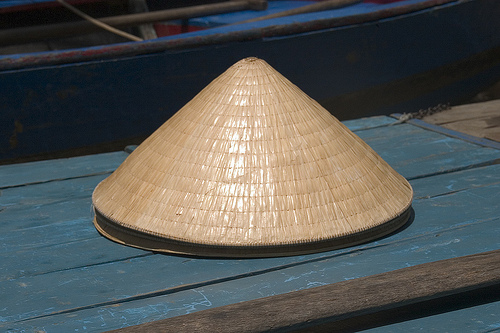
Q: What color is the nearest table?
A: Blue.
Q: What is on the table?
A: Hat.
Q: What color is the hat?
A: Tan.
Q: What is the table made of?
A: Wood.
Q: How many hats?
A: One.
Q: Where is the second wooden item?
A: Behind the blue table.